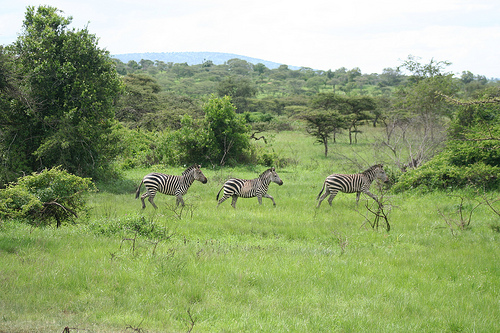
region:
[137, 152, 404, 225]
the zebras are running in the wild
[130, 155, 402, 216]
zebras running in grass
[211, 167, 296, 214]
a yougn zebra in the field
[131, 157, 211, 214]
a large zebra running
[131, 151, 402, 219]
a few zebras chasing each other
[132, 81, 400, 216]
zebras standing in a forest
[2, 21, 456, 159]
forests surrounding an wooded prarie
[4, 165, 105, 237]
a bush on a savannah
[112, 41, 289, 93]
green mountainous forested areas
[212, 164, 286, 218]
small zebra playing in the grass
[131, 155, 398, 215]
zebra family traveling through nature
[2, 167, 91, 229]
bush out on the fertile pasture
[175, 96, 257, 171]
bush out on the fertile pasture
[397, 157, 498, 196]
bush out on the fertile pasture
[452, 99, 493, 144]
bush out on the fertile pasture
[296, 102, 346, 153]
tree out on the fertile pasture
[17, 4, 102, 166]
tree out on the fertile pasture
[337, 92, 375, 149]
tree out on the fertile pasture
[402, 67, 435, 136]
tree out on the fertile pasture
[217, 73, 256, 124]
tree out on the fertile pasture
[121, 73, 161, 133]
tree out on the fertile pasture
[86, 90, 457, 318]
these are zebras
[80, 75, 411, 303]
this is a large field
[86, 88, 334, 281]
the field is open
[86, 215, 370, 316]
the field is tall grass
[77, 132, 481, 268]
there are three zebras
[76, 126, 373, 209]
the zebras are striped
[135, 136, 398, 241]
the zebras are white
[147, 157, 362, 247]
the zebras are black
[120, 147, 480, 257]
the zebras are black and white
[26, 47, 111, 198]
these are tall trees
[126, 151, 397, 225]
three zebras in the field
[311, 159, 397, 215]
zebra walking to the right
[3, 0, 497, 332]
green trees in the field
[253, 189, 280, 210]
front legs of zebra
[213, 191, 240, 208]
back legs of zebra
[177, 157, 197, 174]
mane of zebra on neck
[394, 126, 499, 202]
a bush color is green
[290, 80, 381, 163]
trees with thin trunk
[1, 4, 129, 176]
a green tree is large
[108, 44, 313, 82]
a mountain behind the trees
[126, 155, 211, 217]
Zebra in a field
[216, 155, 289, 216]
Zebra running in a field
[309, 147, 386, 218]
Black and white zebra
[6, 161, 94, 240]
Green tree in a field